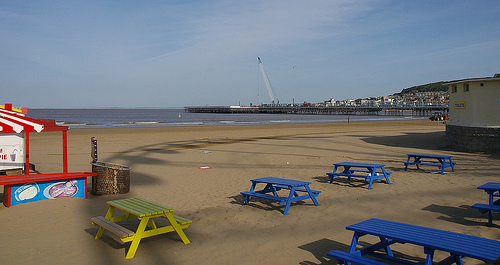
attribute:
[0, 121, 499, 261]
sand — golden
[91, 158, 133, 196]
trash bin — large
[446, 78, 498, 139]
building — creme, brick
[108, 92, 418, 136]
water — blue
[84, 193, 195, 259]
picnic table — yellow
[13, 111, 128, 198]
food stand — red, wooden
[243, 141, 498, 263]
benches — blue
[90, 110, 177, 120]
water — calm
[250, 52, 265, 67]
jet — small